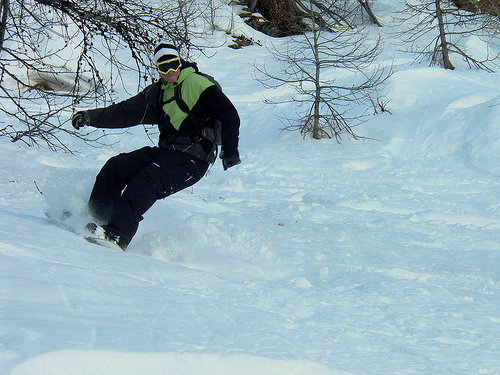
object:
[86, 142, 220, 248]
pants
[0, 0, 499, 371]
snow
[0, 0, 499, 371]
hill side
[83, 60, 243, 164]
jacket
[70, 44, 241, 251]
man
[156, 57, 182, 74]
goggles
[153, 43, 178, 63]
hat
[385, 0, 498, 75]
tree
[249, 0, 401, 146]
tree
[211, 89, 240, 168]
left arm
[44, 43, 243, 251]
right arm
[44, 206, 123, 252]
skis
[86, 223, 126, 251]
foot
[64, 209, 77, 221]
foot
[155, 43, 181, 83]
head